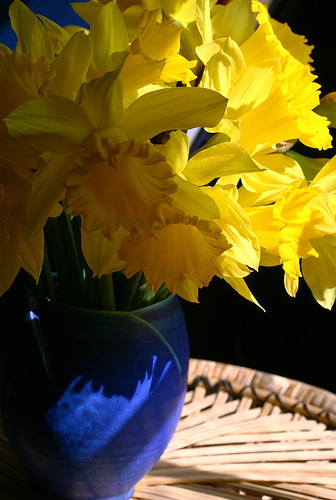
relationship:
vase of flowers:
[17, 293, 192, 485] [4, 41, 325, 295]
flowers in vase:
[4, 41, 325, 295] [17, 293, 192, 485]